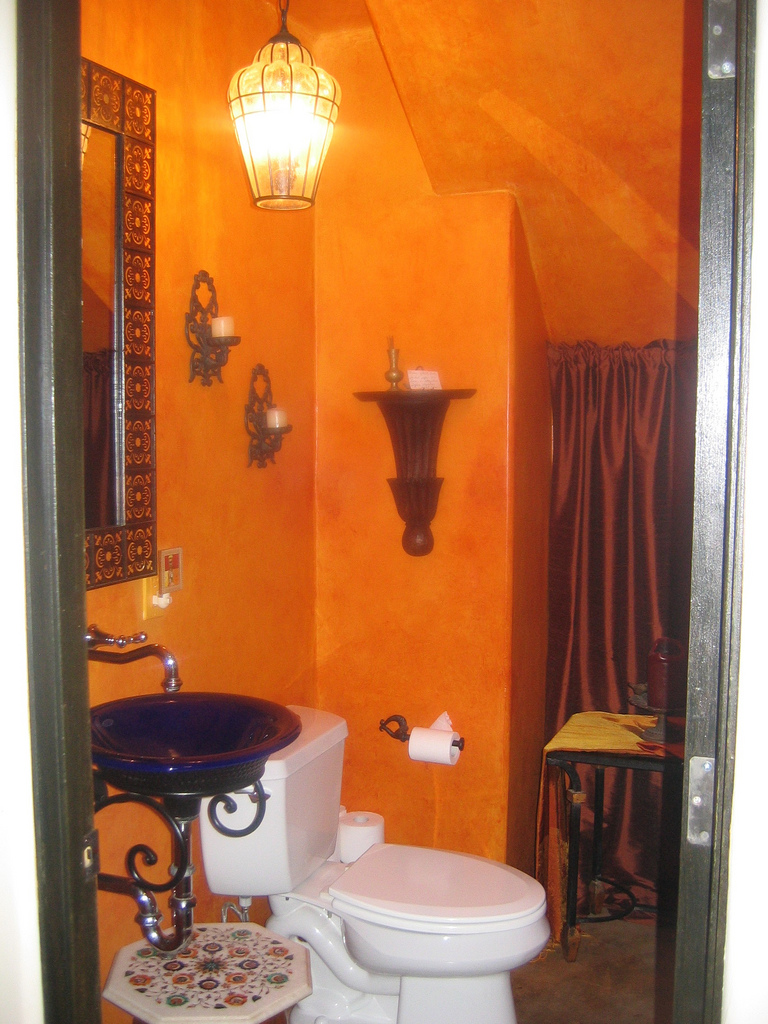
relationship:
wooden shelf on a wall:
[353, 388, 477, 551] [321, 224, 397, 651]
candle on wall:
[207, 312, 234, 341] [274, 227, 374, 609]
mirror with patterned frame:
[89, 134, 118, 520] [124, 79, 157, 578]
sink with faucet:
[77, 674, 310, 877] [83, 616, 188, 703]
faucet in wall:
[83, 616, 188, 703] [85, 565, 227, 757]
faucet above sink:
[83, 616, 188, 702] [91, 684, 305, 796]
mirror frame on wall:
[76, 67, 164, 593] [121, 74, 337, 641]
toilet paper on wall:
[387, 718, 467, 798] [452, 651, 485, 698]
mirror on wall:
[89, 134, 119, 520] [77, 9, 303, 673]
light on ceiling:
[219, 3, 347, 220] [188, 11, 565, 80]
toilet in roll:
[388, 718, 468, 798] [403, 721, 461, 774]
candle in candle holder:
[207, 312, 234, 340] [183, 265, 247, 393]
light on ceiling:
[219, 3, 347, 220] [216, 9, 489, 34]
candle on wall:
[207, 312, 234, 340] [177, 126, 319, 625]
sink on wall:
[77, 674, 310, 877] [71, 125, 537, 980]